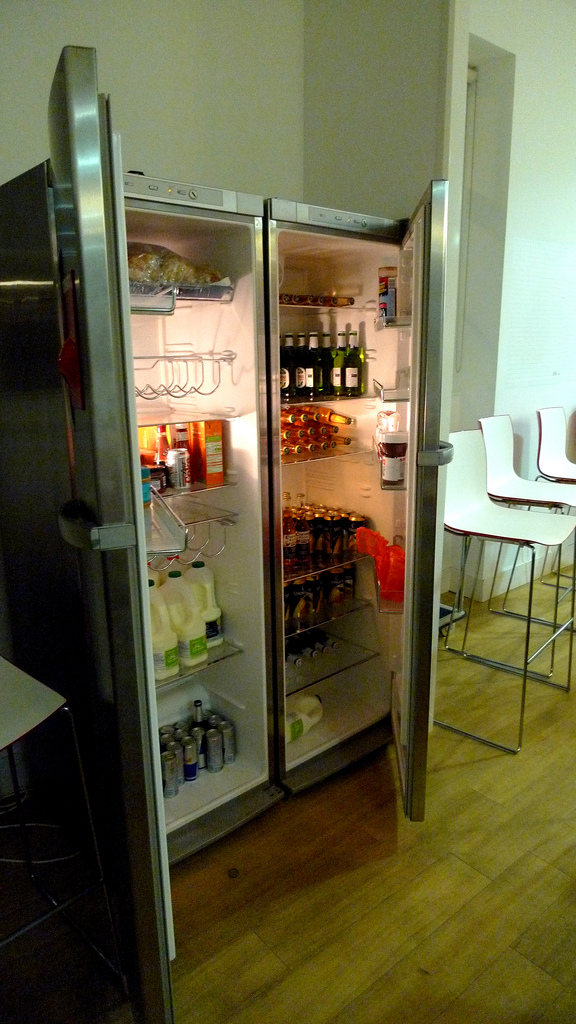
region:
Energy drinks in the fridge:
[150, 707, 243, 801]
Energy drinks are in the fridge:
[145, 708, 243, 801]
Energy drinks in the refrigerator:
[146, 712, 242, 799]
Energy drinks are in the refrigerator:
[148, 711, 248, 800]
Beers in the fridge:
[270, 280, 379, 687]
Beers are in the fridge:
[265, 277, 390, 683]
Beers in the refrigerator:
[271, 283, 396, 671]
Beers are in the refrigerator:
[269, 282, 384, 681]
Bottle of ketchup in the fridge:
[168, 420, 202, 487]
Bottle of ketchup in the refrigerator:
[167, 417, 201, 491]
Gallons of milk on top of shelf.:
[154, 577, 229, 670]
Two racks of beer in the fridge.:
[279, 488, 382, 629]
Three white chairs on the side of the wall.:
[450, 391, 573, 560]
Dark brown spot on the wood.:
[220, 856, 243, 882]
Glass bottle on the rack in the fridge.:
[273, 392, 342, 452]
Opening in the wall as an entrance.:
[449, 17, 508, 454]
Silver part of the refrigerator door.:
[53, 78, 173, 666]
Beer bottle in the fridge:
[303, 329, 322, 394]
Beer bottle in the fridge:
[277, 330, 298, 395]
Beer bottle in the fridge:
[297, 406, 354, 424]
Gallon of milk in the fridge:
[157, 565, 208, 664]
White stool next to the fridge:
[430, 427, 574, 756]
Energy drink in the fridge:
[203, 726, 226, 771]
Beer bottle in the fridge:
[278, 404, 298, 427]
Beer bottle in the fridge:
[290, 407, 312, 425]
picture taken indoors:
[13, 179, 574, 1016]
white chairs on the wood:
[460, 384, 562, 734]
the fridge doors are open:
[55, 229, 487, 939]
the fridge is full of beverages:
[179, 333, 388, 762]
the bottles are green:
[289, 321, 369, 390]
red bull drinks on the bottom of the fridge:
[179, 723, 230, 767]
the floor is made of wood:
[319, 774, 567, 1014]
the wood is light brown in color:
[340, 866, 466, 951]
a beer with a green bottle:
[341, 329, 364, 398]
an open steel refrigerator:
[0, 43, 449, 1022]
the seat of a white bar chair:
[478, 415, 574, 505]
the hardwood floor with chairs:
[166, 562, 573, 1021]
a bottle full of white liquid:
[155, 568, 210, 667]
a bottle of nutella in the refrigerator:
[376, 433, 408, 483]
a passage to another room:
[437, 31, 518, 611]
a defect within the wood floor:
[413, 963, 433, 977]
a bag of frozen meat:
[125, 235, 222, 288]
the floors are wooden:
[244, 813, 525, 952]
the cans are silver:
[153, 711, 269, 803]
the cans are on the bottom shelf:
[151, 686, 271, 835]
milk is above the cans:
[149, 569, 265, 796]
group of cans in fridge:
[161, 697, 246, 799]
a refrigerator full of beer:
[275, 258, 390, 755]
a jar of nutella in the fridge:
[380, 431, 405, 486]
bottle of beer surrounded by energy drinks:
[159, 698, 235, 798]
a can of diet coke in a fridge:
[171, 445, 193, 486]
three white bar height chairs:
[440, 405, 570, 759]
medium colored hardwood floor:
[153, 559, 573, 1023]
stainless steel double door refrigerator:
[5, 44, 461, 1014]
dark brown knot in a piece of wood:
[222, 864, 240, 882]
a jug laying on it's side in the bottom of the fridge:
[287, 693, 324, 742]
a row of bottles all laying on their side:
[278, 291, 353, 307]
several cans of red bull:
[188, 723, 252, 785]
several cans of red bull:
[182, 712, 225, 788]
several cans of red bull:
[162, 724, 195, 802]